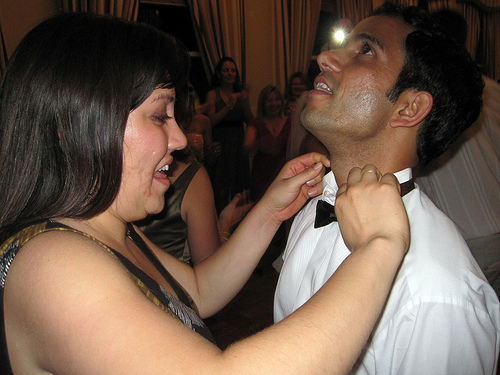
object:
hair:
[1, 16, 166, 233]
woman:
[0, 17, 410, 373]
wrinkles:
[470, 301, 488, 336]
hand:
[333, 162, 410, 254]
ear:
[388, 90, 433, 128]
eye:
[149, 110, 172, 128]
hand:
[257, 150, 330, 220]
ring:
[361, 168, 377, 177]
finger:
[361, 164, 380, 183]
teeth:
[165, 164, 169, 170]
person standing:
[202, 57, 254, 204]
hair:
[382, 6, 484, 164]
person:
[271, 3, 497, 369]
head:
[295, 4, 485, 175]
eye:
[357, 41, 377, 57]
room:
[0, 12, 500, 375]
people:
[285, 72, 312, 150]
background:
[0, 9, 499, 154]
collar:
[324, 167, 411, 199]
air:
[243, 13, 328, 30]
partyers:
[241, 85, 292, 206]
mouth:
[150, 159, 174, 188]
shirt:
[274, 162, 500, 370]